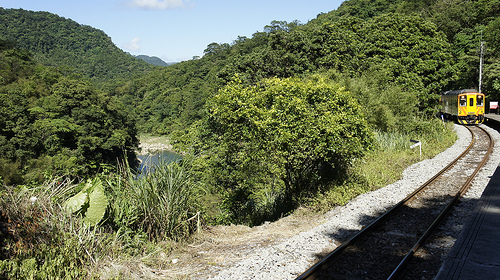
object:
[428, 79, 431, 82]
leaves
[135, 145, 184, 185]
river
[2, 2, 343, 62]
sky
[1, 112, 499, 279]
land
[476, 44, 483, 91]
pole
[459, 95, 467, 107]
windows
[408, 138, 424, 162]
traffic marker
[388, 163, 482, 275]
track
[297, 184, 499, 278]
shadow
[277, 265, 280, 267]
gravel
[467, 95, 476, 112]
door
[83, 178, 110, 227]
leaf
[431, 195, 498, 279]
platform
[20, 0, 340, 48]
clouds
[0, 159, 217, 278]
bush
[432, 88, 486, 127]
train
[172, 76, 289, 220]
tree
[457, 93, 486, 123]
face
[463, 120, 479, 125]
bottom